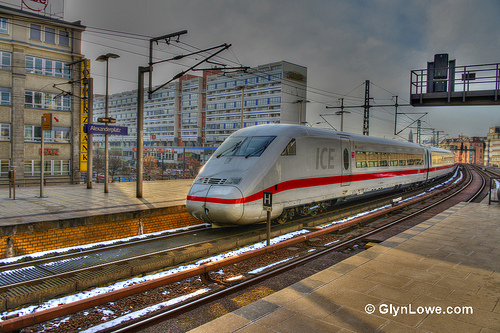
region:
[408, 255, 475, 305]
the sidewalk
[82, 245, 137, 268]
the train tracks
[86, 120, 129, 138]
a blue sign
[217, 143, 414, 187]
a train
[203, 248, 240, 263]
snow on the train tracks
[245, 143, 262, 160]
winshield wipers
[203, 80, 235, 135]
a building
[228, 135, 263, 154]
the windshield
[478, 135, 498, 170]
a building that is tanned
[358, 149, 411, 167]
windows on the train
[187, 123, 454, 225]
ICE train on the tracks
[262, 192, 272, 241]
sign on the track with the letter H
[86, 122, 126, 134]
blue sign on the station platorm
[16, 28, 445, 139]
power lines above the high-speed train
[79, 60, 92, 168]
yellow sign on the building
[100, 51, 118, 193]
light post on the far platform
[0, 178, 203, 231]
far train platform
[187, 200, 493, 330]
near train platform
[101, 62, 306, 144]
white building with the blue between the windows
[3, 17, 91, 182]
5-story building by the train platform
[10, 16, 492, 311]
a train on a track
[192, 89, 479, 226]
a red and silver train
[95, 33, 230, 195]
rail poles on the track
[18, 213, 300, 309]
tracks for the train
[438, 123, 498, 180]
buildings in the background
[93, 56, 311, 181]
buildings near the tracks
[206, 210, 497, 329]
a platform for travelers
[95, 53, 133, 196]
a light pole near the treacks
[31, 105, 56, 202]
a pole in the ground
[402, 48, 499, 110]
a platform for the train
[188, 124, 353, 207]
bullet train on tracks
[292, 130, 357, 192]
ice written on side of train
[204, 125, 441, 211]
train with red stripe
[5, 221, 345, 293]
snow covered train tracks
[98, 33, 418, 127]
train electrical poles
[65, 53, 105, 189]
lettering on side of building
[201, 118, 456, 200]
speeding passenger train on tracks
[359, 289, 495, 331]
web address of photo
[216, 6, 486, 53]
blue and white clouds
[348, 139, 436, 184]
windows on the side of train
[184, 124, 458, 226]
A white and red train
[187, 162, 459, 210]
A red stripe on train.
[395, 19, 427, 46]
A blue sky between clouds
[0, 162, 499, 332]
A train track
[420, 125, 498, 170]
Buildings in the distance.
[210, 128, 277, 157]
Windsheild of plane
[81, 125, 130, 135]
A purple sign.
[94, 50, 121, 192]
A tall street light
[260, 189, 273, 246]
A small sign on a pole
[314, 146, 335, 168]
Word saying "ice" on side of train.